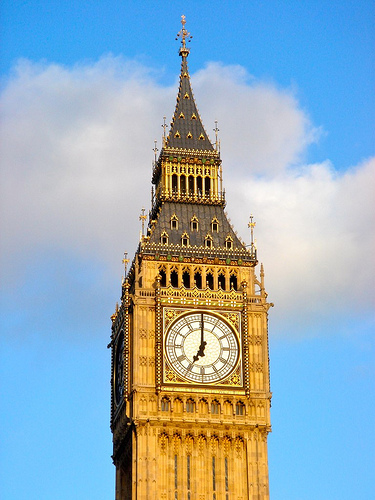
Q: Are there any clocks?
A: Yes, there is a clock.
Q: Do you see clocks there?
A: Yes, there is a clock.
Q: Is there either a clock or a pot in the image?
A: Yes, there is a clock.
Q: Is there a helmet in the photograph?
A: No, there are no helmets.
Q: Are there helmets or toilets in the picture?
A: No, there are no helmets or toilets.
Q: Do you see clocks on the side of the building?
A: Yes, there is a clock on the side of the building.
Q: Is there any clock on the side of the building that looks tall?
A: Yes, there is a clock on the side of the building.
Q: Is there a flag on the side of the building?
A: No, there is a clock on the side of the building.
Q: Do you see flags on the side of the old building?
A: No, there is a clock on the side of the building.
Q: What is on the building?
A: The clock is on the building.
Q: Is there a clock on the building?
A: Yes, there is a clock on the building.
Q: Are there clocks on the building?
A: Yes, there is a clock on the building.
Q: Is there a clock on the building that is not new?
A: Yes, there is a clock on the building.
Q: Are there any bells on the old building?
A: No, there is a clock on the building.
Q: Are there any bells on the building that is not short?
A: No, there is a clock on the building.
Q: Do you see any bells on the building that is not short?
A: No, there is a clock on the building.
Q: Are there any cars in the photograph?
A: No, there are no cars.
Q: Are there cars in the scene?
A: No, there are no cars.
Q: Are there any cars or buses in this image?
A: No, there are no cars or buses.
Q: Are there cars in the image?
A: No, there are no cars.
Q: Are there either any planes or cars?
A: No, there are no cars or planes.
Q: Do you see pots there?
A: No, there are no pots.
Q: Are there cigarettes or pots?
A: No, there are no pots or cigarettes.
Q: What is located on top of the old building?
A: The cross is on top of the building.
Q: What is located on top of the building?
A: The cross is on top of the building.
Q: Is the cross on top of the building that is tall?
A: Yes, the cross is on top of the building.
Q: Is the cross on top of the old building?
A: Yes, the cross is on top of the building.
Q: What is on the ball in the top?
A: The cross is on the ball.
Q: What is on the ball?
A: The cross is on the ball.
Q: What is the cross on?
A: The cross is on the ball.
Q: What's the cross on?
A: The cross is on the ball.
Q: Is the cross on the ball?
A: Yes, the cross is on the ball.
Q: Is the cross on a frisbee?
A: No, the cross is on the ball.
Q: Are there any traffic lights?
A: No, there are no traffic lights.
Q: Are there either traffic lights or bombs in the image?
A: No, there are no traffic lights or bombs.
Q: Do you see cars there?
A: No, there are no cars.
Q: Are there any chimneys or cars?
A: No, there are no cars or chimneys.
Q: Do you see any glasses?
A: No, there are no glasses.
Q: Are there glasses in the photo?
A: No, there are no glasses.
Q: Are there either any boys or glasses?
A: No, there are no glasses or boys.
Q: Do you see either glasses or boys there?
A: No, there are no glasses or boys.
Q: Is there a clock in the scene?
A: Yes, there is a clock.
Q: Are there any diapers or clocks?
A: Yes, there is a clock.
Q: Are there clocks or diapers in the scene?
A: Yes, there is a clock.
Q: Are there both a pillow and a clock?
A: No, there is a clock but no pillows.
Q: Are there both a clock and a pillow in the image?
A: No, there is a clock but no pillows.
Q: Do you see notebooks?
A: No, there are no notebooks.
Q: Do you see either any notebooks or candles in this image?
A: No, there are no notebooks or candles.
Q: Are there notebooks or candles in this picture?
A: No, there are no notebooks or candles.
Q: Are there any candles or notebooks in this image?
A: No, there are no notebooks or candles.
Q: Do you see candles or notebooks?
A: No, there are no notebooks or candles.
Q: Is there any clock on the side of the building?
A: Yes, there is a clock on the side of the building.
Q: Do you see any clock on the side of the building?
A: Yes, there is a clock on the side of the building.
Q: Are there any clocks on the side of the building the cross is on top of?
A: Yes, there is a clock on the side of the building.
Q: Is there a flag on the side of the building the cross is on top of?
A: No, there is a clock on the side of the building.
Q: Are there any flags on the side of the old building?
A: No, there is a clock on the side of the building.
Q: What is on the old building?
A: The clock is on the building.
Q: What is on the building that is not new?
A: The clock is on the building.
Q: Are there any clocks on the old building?
A: Yes, there is a clock on the building.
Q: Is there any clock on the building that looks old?
A: Yes, there is a clock on the building.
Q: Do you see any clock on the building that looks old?
A: Yes, there is a clock on the building.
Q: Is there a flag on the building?
A: No, there is a clock on the building.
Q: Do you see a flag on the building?
A: No, there is a clock on the building.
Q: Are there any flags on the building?
A: No, there is a clock on the building.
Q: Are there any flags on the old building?
A: No, there is a clock on the building.